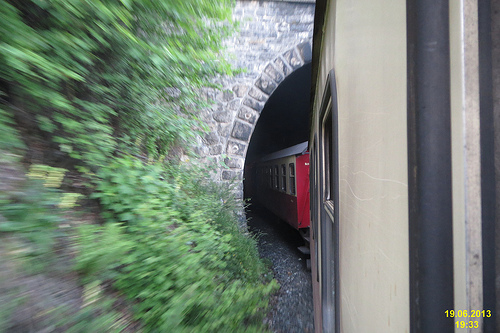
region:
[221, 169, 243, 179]
grey brick on tunnel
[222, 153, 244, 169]
grey brick on tunnel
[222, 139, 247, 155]
grey brick on tunnel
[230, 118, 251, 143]
grey brick on tunnel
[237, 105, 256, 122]
grey brick on tunnel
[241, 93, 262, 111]
grey brick on tunnel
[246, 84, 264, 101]
grey brick on tunnel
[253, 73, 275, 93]
grey brick on tunnel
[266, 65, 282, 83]
grey brick on tunnel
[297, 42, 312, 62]
grey brick on tunnel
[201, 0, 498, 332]
a train going into a tunnel.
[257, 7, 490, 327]
Train entering a tunnel.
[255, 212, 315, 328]
Crushed stones alongside of the railways.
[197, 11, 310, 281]
Entrance of the tunnel is nicely built of stones.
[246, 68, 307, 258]
Tunnel is very dark.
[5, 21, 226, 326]
Green climbing plants alongside the railways.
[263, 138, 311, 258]
Train is red with small windows.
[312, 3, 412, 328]
Top half of the side train is beige.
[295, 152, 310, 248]
Back of the train is red.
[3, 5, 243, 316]
Plants near the railways grow wildly.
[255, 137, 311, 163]
Roof of the train is grey.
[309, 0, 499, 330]
A train car outside the tunnel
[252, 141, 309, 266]
Part of the train still inside the tunnel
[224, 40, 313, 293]
Mouth of the train tunnel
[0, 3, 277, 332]
Vegetation by the side of the tunnel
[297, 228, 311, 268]
Footboard to climb into the car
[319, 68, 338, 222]
Window of the car outside the tunnel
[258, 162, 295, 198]
A row of windows visible on the train cab inside the tunnel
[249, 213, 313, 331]
Gravel on which the track is laid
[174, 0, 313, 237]
Part of the visible stone wall of the tunnel mouth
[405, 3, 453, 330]
Gasket around the door frame